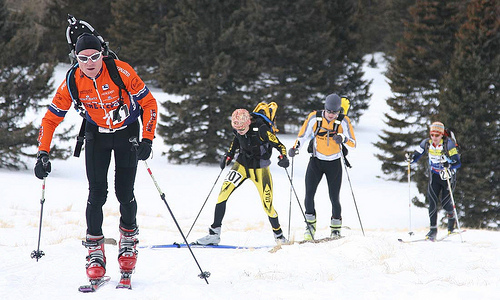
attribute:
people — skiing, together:
[35, 31, 462, 280]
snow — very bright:
[1, 52, 500, 298]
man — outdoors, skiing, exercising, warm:
[35, 33, 157, 278]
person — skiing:
[289, 92, 355, 240]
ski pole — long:
[129, 135, 211, 285]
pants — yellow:
[213, 159, 283, 233]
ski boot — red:
[83, 234, 107, 279]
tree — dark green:
[0, 0, 85, 170]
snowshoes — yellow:
[253, 101, 277, 123]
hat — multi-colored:
[231, 108, 251, 129]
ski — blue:
[136, 243, 274, 249]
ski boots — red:
[82, 225, 138, 280]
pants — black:
[304, 156, 343, 219]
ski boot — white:
[197, 225, 221, 245]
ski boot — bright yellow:
[303, 213, 315, 242]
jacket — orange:
[37, 56, 157, 152]